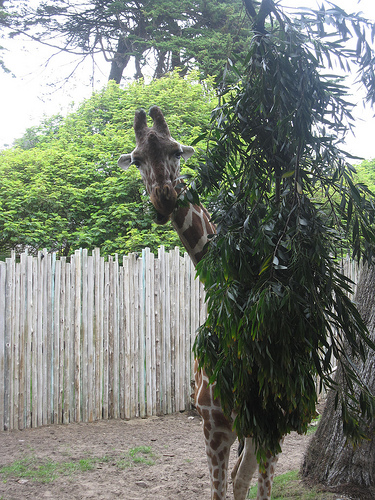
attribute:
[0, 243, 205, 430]
fence — wooden, made of trees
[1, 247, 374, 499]
enclosure — giraffe enclosure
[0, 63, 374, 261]
tree — leafy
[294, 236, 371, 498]
bark — thick, brown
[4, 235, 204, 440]
logs — asymetrical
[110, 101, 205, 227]
head — giraffe's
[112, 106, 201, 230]
face — giraffe's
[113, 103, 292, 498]
giraffe — tall, eating, brown, white, adult, looking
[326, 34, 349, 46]
leaf — green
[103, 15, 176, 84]
tree — green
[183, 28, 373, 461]
branch — hanging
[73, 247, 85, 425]
wood — brown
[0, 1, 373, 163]
sky — white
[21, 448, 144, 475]
grass — green